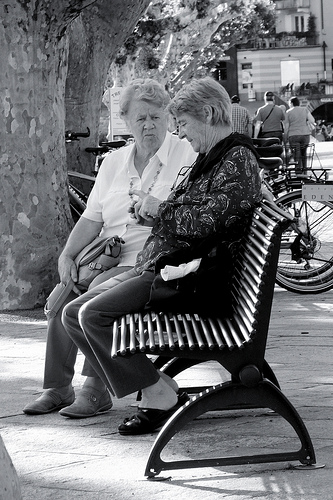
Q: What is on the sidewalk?
A: Bench.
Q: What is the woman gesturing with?
A: Hands.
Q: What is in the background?
A: Building.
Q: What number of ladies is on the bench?
A: Two.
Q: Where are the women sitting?
A: Bench.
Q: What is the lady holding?
A: Handbag.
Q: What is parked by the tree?
A: Bicycles.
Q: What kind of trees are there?
A: Sycamore.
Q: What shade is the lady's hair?
A: Light.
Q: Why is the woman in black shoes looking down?
A: To look at a cell phone.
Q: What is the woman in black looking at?
A: Cellphone.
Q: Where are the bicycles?
A: Behind the side of the bench.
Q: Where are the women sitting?
A: On a bench.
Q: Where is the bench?
A: In a park.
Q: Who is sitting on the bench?
A: Two old women.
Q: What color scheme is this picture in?
A: Black and white.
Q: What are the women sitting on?
A: A bench.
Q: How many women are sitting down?
A: Two.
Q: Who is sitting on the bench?
A: Two women.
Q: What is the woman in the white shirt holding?
A: A purse.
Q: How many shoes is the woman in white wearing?
A: Two.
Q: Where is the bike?
A: Behind the women.